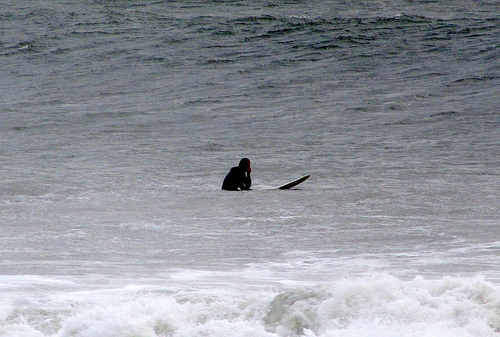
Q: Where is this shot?
A: Ocean.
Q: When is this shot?
A: Daytime.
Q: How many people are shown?
A: 1.